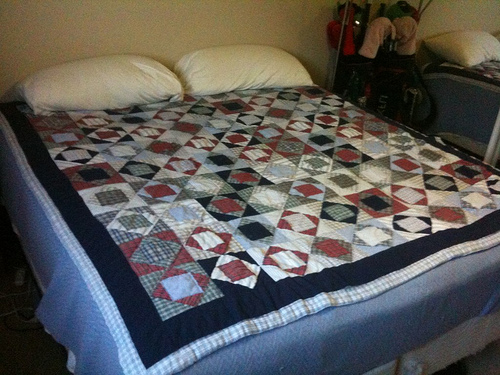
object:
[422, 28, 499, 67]
pillow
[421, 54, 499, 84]
bed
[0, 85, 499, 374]
quilt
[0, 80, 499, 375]
bed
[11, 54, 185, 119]
pillow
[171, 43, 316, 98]
pillow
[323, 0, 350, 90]
golf clubs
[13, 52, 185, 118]
case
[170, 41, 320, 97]
case